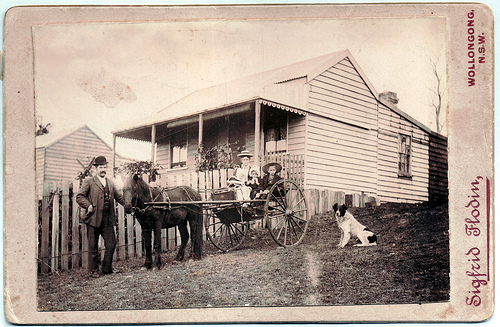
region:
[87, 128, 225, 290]
the horse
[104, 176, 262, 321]
the horse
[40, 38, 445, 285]
vintage photo of family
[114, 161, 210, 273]
horse pulling a carriage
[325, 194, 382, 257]
dog sitting on grass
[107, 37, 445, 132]
roof of a house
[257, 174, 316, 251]
large wheel of a carriage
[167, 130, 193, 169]
window of a house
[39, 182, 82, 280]
wooden fence by house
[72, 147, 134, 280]
man standing by horse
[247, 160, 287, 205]
children sitting in carriage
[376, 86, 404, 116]
chimney of a house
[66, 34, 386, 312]
turn of the century family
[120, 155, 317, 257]
horse and buggey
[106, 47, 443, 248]
old home with picket fence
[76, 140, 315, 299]
husband, wife and child at home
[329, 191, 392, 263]
white and black spotted dog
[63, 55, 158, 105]
cloudy sky in the background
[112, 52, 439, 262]
modest house in the foreground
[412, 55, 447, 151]
tree growing in the back yard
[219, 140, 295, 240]
little boy and mother sitting in carriage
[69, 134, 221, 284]
a man holding the reigns of a carriage horse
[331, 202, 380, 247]
a black and white dog sitting in the yard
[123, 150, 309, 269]
a horse and buggy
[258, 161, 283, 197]
a young boy with a wide rimmed hat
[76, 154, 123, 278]
a man with a bowler hat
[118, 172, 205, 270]
a small horse pulling a carriage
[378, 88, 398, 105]
a chimney stack on top of the house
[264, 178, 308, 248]
the buggies large spoke wheel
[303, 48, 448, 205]
wooden slats on the side of the house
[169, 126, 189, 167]
reflection of sunlight on the glass windows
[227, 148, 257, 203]
a lady wearing 1830's fashion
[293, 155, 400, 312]
the dog is sitting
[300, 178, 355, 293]
the dog is sitting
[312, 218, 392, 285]
the dog is sitting